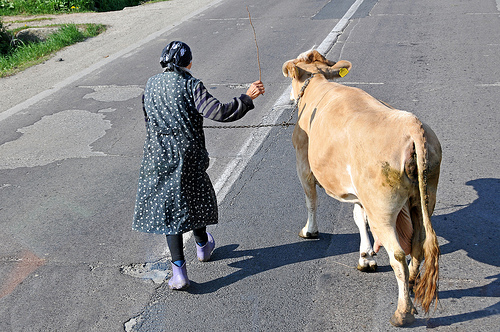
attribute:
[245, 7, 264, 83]
stick — small, brown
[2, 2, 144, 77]
patch — small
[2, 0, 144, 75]
grass — green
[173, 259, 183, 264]
sock — blue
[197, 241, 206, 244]
sock — blue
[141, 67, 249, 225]
coat — blue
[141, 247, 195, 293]
sneakers — gray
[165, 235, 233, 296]
shoes — purple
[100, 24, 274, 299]
lady — white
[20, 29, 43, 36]
gray rock — small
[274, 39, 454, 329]
cow — brown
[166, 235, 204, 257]
socks — blue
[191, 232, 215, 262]
shoe — purple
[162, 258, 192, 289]
shoe — purple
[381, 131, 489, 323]
tail — brown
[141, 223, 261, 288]
socks — blue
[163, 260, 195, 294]
boot — purple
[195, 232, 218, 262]
boot — purple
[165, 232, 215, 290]
boots — purple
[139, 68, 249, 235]
jacket — blue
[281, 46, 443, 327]
cow — brown